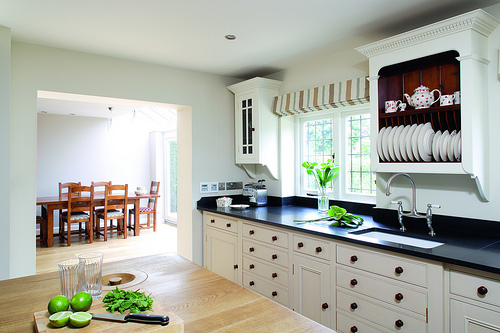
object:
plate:
[417, 122, 437, 162]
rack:
[377, 109, 464, 163]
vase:
[317, 187, 328, 215]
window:
[294, 103, 378, 207]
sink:
[348, 227, 446, 250]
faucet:
[384, 172, 440, 237]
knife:
[87, 311, 171, 327]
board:
[32, 292, 183, 333]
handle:
[121, 313, 169, 327]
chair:
[57, 181, 93, 246]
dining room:
[35, 90, 178, 276]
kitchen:
[0, 0, 500, 331]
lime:
[44, 310, 92, 329]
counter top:
[195, 192, 500, 333]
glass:
[57, 257, 86, 301]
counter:
[0, 250, 337, 333]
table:
[36, 195, 160, 248]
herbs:
[103, 285, 154, 314]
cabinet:
[195, 7, 500, 333]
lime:
[70, 292, 94, 312]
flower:
[301, 158, 339, 188]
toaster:
[242, 179, 268, 207]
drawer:
[333, 259, 428, 322]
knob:
[350, 255, 358, 262]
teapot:
[404, 84, 442, 110]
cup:
[78, 251, 102, 299]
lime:
[47, 294, 70, 314]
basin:
[348, 227, 445, 249]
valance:
[273, 75, 371, 119]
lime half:
[67, 309, 92, 329]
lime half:
[45, 309, 75, 329]